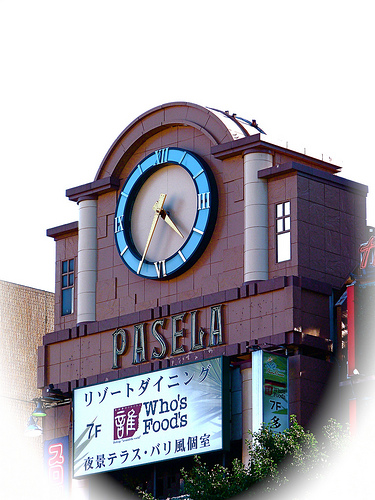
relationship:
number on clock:
[151, 257, 169, 277] [108, 141, 222, 284]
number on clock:
[193, 191, 210, 206] [108, 141, 222, 284]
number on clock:
[154, 146, 168, 165] [108, 141, 222, 284]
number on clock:
[110, 214, 125, 232] [108, 141, 222, 284]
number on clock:
[114, 215, 124, 234] [111, 147, 216, 281]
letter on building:
[208, 307, 222, 345] [33, 100, 368, 499]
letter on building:
[187, 307, 206, 353] [33, 100, 368, 499]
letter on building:
[168, 311, 189, 356] [21, 76, 366, 441]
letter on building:
[150, 319, 169, 362] [33, 100, 368, 499]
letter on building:
[108, 324, 131, 372] [33, 100, 368, 499]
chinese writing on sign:
[81, 366, 211, 409] [70, 355, 225, 478]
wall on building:
[54, 108, 298, 358] [33, 100, 368, 499]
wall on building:
[2, 283, 52, 396] [0, 279, 53, 435]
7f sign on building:
[251, 347, 291, 447] [33, 100, 368, 499]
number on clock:
[149, 140, 172, 170] [108, 141, 222, 284]